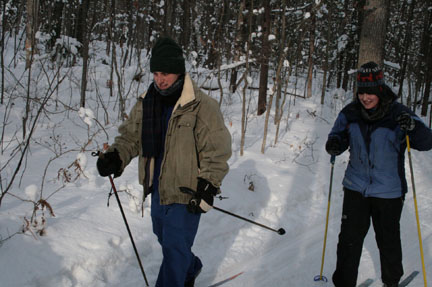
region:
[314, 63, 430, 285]
woman on skies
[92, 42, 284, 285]
man on skies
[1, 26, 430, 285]
floor covered in snow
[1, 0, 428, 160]
trees behind man and woman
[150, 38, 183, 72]
black hat on man's head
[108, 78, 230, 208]
tan jacket man is wearing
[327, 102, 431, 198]
blue and black jacket woman is wearing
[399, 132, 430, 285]
yellow ski stick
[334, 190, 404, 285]
black pants woman is wearing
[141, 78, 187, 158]
scarf man is wearing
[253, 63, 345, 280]
the snow is white and clear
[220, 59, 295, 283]
the snow is white and clear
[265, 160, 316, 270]
the snow is white and clear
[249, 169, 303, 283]
the snow is white and clear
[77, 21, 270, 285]
guy walking with ski poles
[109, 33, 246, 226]
guy wearing brown jacket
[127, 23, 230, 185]
guy wearing black hat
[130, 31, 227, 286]
guy wearing black and white glove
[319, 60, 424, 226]
girl wearing blue and black jacket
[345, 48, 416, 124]
black, red, and white hat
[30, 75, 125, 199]
branches with snow on them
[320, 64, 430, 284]
girl using yellow ski poles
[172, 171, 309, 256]
carrying black ski pole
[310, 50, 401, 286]
girl wearing black pants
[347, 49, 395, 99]
red gray and white hat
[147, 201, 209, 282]
pair of blue jeans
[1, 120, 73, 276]
white snow and branches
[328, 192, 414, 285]
pair of black pants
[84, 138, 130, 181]
one black glove on hand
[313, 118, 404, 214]
black and blue jacket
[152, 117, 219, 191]
tan jacket on person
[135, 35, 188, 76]
black warm snow hat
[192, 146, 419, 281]
black and yellow ski poles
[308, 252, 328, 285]
bottom of a ski pole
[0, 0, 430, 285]
a daytime picture of a couple cross country skiing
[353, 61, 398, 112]
the girl is wearing a wool knit cap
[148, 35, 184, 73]
the man is wearing a black wool knit cap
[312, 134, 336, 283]
the lady is holding yellow and black ski poles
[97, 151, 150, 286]
the man is holding black ski poles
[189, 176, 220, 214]
the man is wearing black and beige mittens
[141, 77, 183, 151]
the man is wearing a black knit scarf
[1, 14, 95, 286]
snow is piled up in the forest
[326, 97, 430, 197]
the girl is wearing a blue ski jacket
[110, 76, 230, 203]
the man is wearing a brown winter jacket